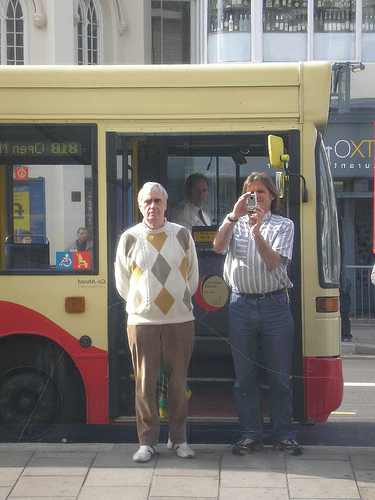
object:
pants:
[126, 321, 193, 446]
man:
[115, 181, 200, 462]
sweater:
[114, 217, 199, 327]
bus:
[0, 59, 364, 442]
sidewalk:
[0, 442, 375, 498]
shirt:
[219, 210, 295, 294]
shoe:
[133, 445, 158, 462]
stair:
[195, 336, 231, 424]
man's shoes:
[233, 438, 264, 456]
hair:
[242, 170, 280, 213]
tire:
[0, 340, 84, 442]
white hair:
[137, 181, 168, 217]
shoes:
[273, 439, 304, 454]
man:
[213, 172, 303, 455]